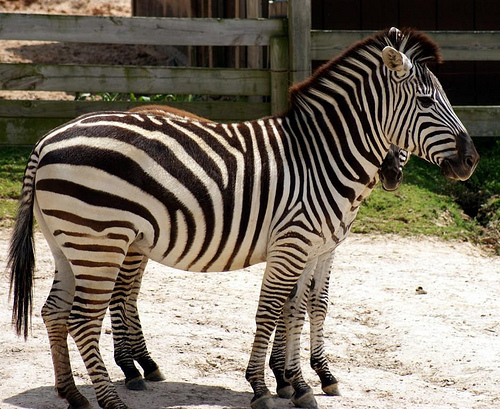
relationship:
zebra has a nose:
[5, 25, 482, 408] [442, 140, 481, 187]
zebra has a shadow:
[5, 25, 482, 408] [3, 374, 313, 406]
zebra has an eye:
[5, 25, 482, 408] [416, 92, 431, 108]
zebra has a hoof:
[5, 25, 482, 408] [248, 389, 279, 407]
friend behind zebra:
[108, 104, 411, 399] [5, 25, 482, 408]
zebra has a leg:
[5, 25, 482, 408] [245, 214, 324, 394]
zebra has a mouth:
[5, 25, 482, 408] [444, 156, 465, 186]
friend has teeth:
[108, 104, 411, 399] [381, 179, 401, 194]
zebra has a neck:
[5, 25, 482, 408] [288, 45, 383, 225]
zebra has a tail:
[5, 25, 482, 408] [4, 156, 43, 341]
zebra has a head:
[5, 25, 482, 408] [378, 21, 483, 184]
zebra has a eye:
[5, 25, 482, 408] [416, 92, 431, 108]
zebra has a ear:
[5, 25, 482, 408] [378, 45, 413, 79]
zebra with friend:
[5, 25, 482, 408] [108, 104, 411, 399]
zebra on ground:
[5, 25, 482, 408] [1, 236, 498, 409]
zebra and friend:
[5, 25, 482, 408] [108, 104, 411, 399]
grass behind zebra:
[1, 147, 496, 233] [5, 25, 482, 408]